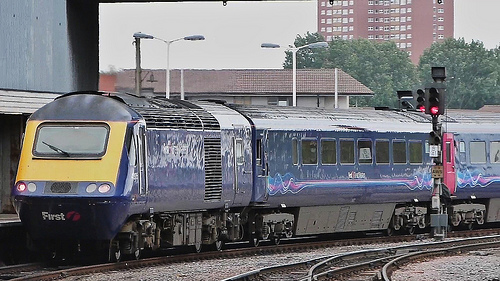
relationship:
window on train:
[32, 122, 109, 157] [8, 90, 499, 264]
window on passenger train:
[318, 137, 338, 166] [11, 64, 451, 249]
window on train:
[299, 138, 317, 165] [12, 85, 496, 245]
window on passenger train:
[376, 140, 393, 165] [12, 85, 496, 245]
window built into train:
[318, 134, 340, 169] [8, 90, 499, 264]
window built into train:
[349, 135, 384, 169] [8, 90, 499, 264]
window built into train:
[406, 138, 426, 167] [8, 90, 499, 264]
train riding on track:
[12, 85, 496, 245] [2, 224, 484, 278]